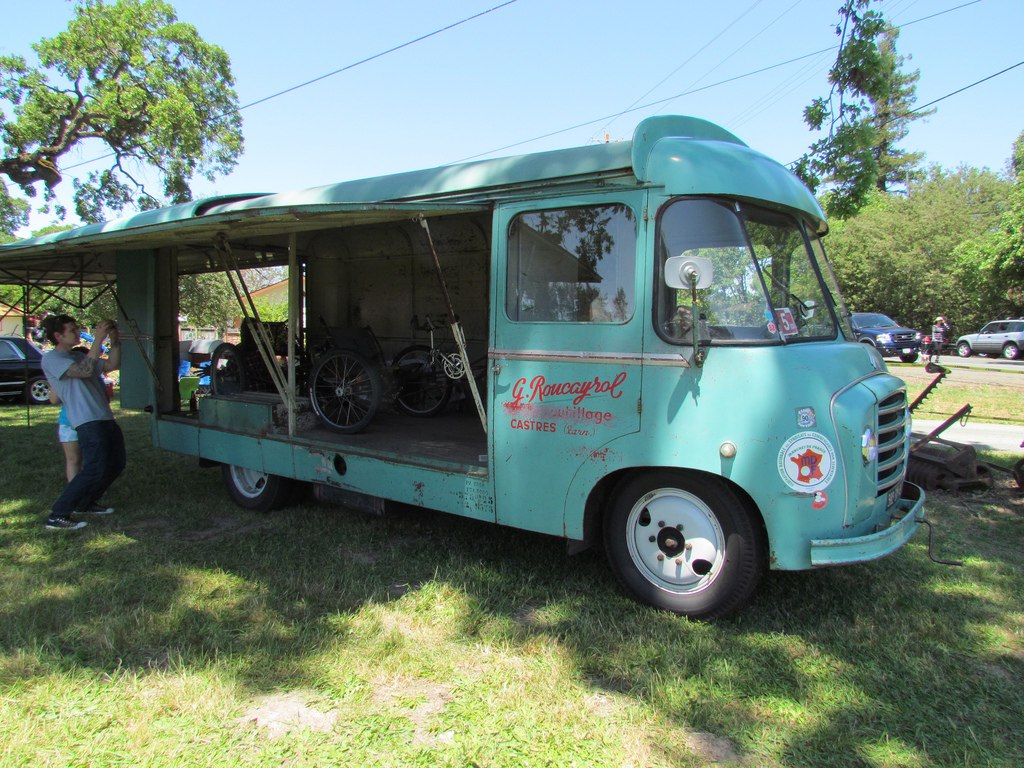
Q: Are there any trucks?
A: Yes, there is a truck.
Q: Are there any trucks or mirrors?
A: Yes, there is a truck.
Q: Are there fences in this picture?
A: No, there are no fences.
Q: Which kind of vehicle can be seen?
A: The vehicle is a truck.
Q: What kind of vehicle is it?
A: The vehicle is a truck.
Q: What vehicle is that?
A: This is a truck.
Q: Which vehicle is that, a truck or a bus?
A: This is a truck.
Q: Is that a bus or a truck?
A: That is a truck.